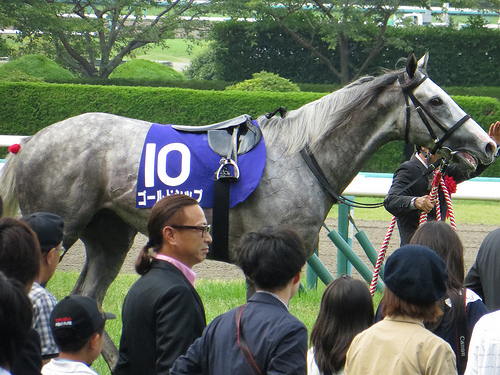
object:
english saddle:
[173, 113, 262, 183]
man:
[111, 195, 212, 375]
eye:
[428, 94, 443, 108]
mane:
[257, 56, 428, 158]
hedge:
[0, 82, 500, 178]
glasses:
[167, 220, 212, 237]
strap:
[232, 304, 260, 375]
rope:
[365, 169, 455, 296]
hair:
[310, 275, 375, 375]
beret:
[385, 242, 451, 305]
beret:
[16, 211, 67, 250]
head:
[396, 48, 496, 173]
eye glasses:
[171, 223, 212, 237]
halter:
[396, 71, 470, 155]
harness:
[134, 113, 266, 265]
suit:
[165, 288, 309, 375]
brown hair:
[134, 193, 199, 275]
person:
[15, 211, 64, 369]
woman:
[340, 243, 460, 375]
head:
[378, 243, 450, 317]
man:
[155, 225, 306, 375]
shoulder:
[204, 304, 244, 343]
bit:
[441, 146, 457, 157]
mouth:
[448, 144, 483, 175]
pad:
[131, 119, 266, 209]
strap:
[210, 173, 231, 262]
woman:
[304, 274, 374, 375]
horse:
[0, 52, 497, 373]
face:
[395, 56, 497, 173]